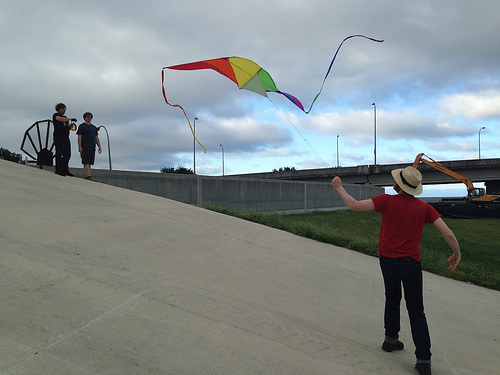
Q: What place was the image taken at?
A: It was taken at the park.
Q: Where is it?
A: This is at the park.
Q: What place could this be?
A: It is a park.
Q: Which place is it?
A: It is a park.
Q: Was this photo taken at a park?
A: Yes, it was taken in a park.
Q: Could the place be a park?
A: Yes, it is a park.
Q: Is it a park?
A: Yes, it is a park.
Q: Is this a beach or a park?
A: It is a park.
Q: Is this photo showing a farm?
A: No, the picture is showing a park.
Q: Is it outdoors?
A: Yes, it is outdoors.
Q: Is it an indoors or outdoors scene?
A: It is outdoors.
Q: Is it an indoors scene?
A: No, it is outdoors.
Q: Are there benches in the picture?
A: No, there are no benches.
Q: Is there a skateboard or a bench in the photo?
A: No, there are no benches or skateboards.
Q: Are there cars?
A: No, there are no cars.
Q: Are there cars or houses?
A: No, there are no cars or houses.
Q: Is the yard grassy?
A: Yes, the yard is grassy.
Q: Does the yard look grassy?
A: Yes, the yard is grassy.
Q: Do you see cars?
A: No, there are no cars.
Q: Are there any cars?
A: No, there are no cars.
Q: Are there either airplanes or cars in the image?
A: No, there are no cars or airplanes.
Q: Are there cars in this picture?
A: No, there are no cars.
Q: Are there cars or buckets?
A: No, there are no cars or buckets.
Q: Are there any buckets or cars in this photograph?
A: No, there are no cars or buckets.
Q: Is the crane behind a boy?
A: Yes, the crane is behind a boy.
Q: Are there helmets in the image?
A: No, there are no helmets.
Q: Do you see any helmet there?
A: No, there are no helmets.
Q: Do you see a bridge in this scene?
A: Yes, there is a bridge.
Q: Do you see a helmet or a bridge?
A: Yes, there is a bridge.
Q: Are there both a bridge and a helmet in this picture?
A: No, there is a bridge but no helmets.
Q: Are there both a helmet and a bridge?
A: No, there is a bridge but no helmets.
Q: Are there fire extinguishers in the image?
A: No, there are no fire extinguishers.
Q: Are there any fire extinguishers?
A: No, there are no fire extinguishers.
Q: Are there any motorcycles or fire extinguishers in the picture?
A: No, there are no fire extinguishers or motorcycles.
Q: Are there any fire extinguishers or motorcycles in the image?
A: No, there are no fire extinguishers or motorcycles.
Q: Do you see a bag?
A: No, there are no bags.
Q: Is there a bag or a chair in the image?
A: No, there are no bags or chairs.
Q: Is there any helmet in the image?
A: No, there are no helmets.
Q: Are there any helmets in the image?
A: No, there are no helmets.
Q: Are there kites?
A: Yes, there is a kite.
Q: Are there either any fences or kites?
A: Yes, there is a kite.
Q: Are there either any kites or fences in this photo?
A: Yes, there is a kite.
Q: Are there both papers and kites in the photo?
A: No, there is a kite but no papers.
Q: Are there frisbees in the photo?
A: No, there are no frisbees.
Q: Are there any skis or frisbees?
A: No, there are no frisbees or skis.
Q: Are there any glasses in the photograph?
A: No, there are no glasses.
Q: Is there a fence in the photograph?
A: Yes, there is a fence.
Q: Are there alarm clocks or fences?
A: Yes, there is a fence.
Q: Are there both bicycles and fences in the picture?
A: No, there is a fence but no bikes.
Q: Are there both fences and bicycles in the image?
A: No, there is a fence but no bikes.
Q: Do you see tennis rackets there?
A: No, there are no tennis rackets.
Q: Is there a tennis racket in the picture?
A: No, there are no rackets.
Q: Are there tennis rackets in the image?
A: No, there are no tennis rackets.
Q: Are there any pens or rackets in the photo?
A: No, there are no rackets or pens.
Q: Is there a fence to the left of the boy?
A: Yes, there is a fence to the left of the boy.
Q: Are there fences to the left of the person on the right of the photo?
A: Yes, there is a fence to the left of the boy.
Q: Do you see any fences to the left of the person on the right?
A: Yes, there is a fence to the left of the boy.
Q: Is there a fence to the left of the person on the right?
A: Yes, there is a fence to the left of the boy.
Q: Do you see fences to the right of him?
A: No, the fence is to the left of the boy.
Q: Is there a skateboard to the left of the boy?
A: No, there is a fence to the left of the boy.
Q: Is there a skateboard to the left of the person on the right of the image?
A: No, there is a fence to the left of the boy.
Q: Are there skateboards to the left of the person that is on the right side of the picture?
A: No, there is a fence to the left of the boy.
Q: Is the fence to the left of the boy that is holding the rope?
A: Yes, the fence is to the left of the boy.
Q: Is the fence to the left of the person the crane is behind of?
A: Yes, the fence is to the left of the boy.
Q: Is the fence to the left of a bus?
A: No, the fence is to the left of the boy.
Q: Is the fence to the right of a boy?
A: No, the fence is to the left of a boy.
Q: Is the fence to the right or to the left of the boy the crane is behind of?
A: The fence is to the left of the boy.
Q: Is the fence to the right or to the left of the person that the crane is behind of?
A: The fence is to the left of the boy.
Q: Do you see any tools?
A: No, there are no tools.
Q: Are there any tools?
A: No, there are no tools.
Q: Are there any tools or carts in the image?
A: No, there are no tools or carts.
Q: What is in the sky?
A: The clouds are in the sky.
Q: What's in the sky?
A: The clouds are in the sky.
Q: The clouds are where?
A: The clouds are in the sky.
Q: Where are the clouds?
A: The clouds are in the sky.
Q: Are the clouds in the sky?
A: Yes, the clouds are in the sky.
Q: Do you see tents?
A: No, there are no tents.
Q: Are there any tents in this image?
A: No, there are no tents.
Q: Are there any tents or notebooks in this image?
A: No, there are no tents or notebooks.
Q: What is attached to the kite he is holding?
A: The rope is attached to the kite.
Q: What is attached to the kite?
A: The rope is attached to the kite.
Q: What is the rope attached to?
A: The rope is attached to the kite.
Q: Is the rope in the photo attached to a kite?
A: Yes, the rope is attached to a kite.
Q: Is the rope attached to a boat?
A: No, the rope is attached to a kite.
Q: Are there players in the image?
A: No, there are no players.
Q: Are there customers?
A: No, there are no customers.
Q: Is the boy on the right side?
A: Yes, the boy is on the right of the image.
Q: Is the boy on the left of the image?
A: No, the boy is on the right of the image.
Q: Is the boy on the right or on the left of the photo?
A: The boy is on the right of the image.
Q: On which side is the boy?
A: The boy is on the right of the image.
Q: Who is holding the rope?
A: The boy is holding the rope.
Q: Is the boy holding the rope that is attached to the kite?
A: Yes, the boy is holding the rope.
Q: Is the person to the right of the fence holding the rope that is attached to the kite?
A: Yes, the boy is holding the rope.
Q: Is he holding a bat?
A: No, the boy is holding the rope.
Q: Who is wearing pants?
A: The boy is wearing pants.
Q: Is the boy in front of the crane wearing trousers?
A: Yes, the boy is wearing trousers.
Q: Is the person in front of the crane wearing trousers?
A: Yes, the boy is wearing trousers.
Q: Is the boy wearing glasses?
A: No, the boy is wearing trousers.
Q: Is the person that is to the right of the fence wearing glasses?
A: No, the boy is wearing trousers.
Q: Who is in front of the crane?
A: The boy is in front of the crane.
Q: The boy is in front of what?
A: The boy is in front of the crane.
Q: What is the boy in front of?
A: The boy is in front of the crane.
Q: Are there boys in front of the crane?
A: Yes, there is a boy in front of the crane.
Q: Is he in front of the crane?
A: Yes, the boy is in front of the crane.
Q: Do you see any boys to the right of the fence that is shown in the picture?
A: Yes, there is a boy to the right of the fence.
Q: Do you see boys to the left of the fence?
A: No, the boy is to the right of the fence.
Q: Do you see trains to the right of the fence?
A: No, there is a boy to the right of the fence.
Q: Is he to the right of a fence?
A: Yes, the boy is to the right of a fence.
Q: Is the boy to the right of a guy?
A: No, the boy is to the right of a fence.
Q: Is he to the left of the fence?
A: No, the boy is to the right of the fence.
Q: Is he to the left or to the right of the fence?
A: The boy is to the right of the fence.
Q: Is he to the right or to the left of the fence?
A: The boy is to the right of the fence.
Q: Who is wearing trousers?
A: The boy is wearing trousers.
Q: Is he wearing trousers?
A: Yes, the boy is wearing trousers.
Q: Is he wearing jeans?
A: No, the boy is wearing trousers.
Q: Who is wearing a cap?
A: The boy is wearing a cap.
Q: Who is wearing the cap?
A: The boy is wearing a cap.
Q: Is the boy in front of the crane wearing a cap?
A: Yes, the boy is wearing a cap.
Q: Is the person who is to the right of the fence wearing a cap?
A: Yes, the boy is wearing a cap.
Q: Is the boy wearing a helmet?
A: No, the boy is wearing a cap.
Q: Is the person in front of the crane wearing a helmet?
A: No, the boy is wearing a cap.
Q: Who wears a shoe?
A: The boy wears a shoe.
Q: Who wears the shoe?
A: The boy wears a shoe.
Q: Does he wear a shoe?
A: Yes, the boy wears a shoe.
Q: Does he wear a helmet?
A: No, the boy wears a shoe.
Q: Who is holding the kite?
A: The boy is holding the kite.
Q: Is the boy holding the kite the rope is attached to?
A: Yes, the boy is holding the kite.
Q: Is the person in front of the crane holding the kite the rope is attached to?
A: Yes, the boy is holding the kite.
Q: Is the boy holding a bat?
A: No, the boy is holding the kite.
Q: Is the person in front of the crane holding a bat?
A: No, the boy is holding the kite.